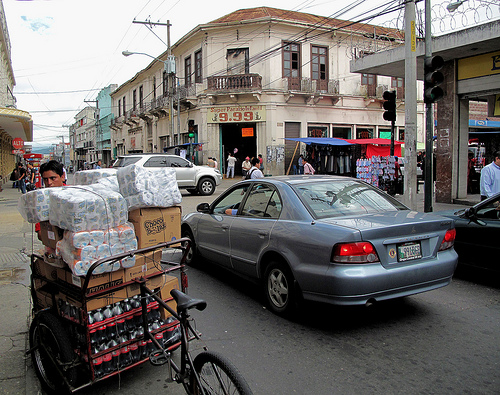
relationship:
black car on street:
[442, 188, 499, 293] [81, 182, 498, 392]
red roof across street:
[343, 136, 405, 146] [81, 182, 498, 392]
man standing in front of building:
[226, 154, 238, 179] [39, 9, 408, 319]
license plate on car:
[394, 243, 427, 263] [186, 187, 420, 311]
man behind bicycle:
[226, 154, 238, 179] [130, 277, 255, 392]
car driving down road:
[283, 175, 383, 280] [0, 178, 500, 395]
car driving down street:
[180, 174, 459, 315] [81, 182, 498, 392]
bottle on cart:
[92, 302, 102, 342] [21, 236, 260, 392]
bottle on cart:
[90, 334, 103, 379] [21, 236, 260, 392]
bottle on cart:
[98, 331, 115, 375] [21, 236, 260, 392]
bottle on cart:
[136, 322, 152, 366] [21, 236, 260, 392]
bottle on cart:
[120, 294, 135, 334] [21, 236, 260, 392]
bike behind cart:
[26, 238, 253, 395] [22, 236, 202, 393]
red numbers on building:
[217, 109, 256, 124] [109, 5, 424, 177]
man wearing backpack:
[240, 152, 271, 178] [241, 165, 255, 183]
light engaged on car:
[443, 228, 457, 240] [180, 174, 459, 315]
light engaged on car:
[338, 239, 373, 256] [180, 174, 459, 315]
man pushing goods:
[38, 160, 72, 189] [49, 184, 128, 229]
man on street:
[38, 160, 72, 189] [0, 174, 497, 390]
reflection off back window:
[293, 175, 406, 215] [283, 174, 411, 221]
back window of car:
[283, 174, 411, 221] [180, 174, 459, 315]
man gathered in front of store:
[223, 151, 236, 179] [199, 104, 424, 183]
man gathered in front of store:
[239, 154, 252, 175] [199, 104, 424, 183]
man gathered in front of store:
[230, 146, 240, 160] [199, 104, 424, 183]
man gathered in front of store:
[255, 153, 265, 170] [199, 104, 424, 183]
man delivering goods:
[34, 160, 71, 241] [13, 167, 181, 377]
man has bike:
[34, 160, 71, 241] [26, 238, 253, 395]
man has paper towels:
[34, 160, 71, 241] [17, 167, 180, 274]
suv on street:
[74, 148, 224, 195] [171, 176, 494, 393]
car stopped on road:
[180, 174, 459, 315] [97, 194, 497, 391]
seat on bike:
[168, 285, 208, 314] [26, 236, 256, 393]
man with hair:
[34, 160, 71, 241] [38, 158, 65, 178]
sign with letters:
[208, 99, 273, 124] [206, 103, 265, 112]